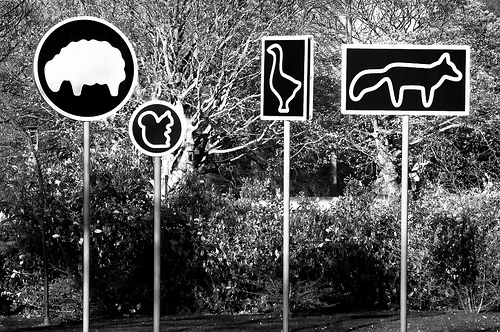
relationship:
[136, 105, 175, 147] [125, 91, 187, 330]
squirrel drawn on sign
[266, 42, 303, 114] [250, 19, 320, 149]
bird drawn on sign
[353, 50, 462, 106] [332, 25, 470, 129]
fox drawn on sign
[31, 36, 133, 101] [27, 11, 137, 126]
sheep drawn on sign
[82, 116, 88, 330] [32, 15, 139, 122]
pole holding up black sign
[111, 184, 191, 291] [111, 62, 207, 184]
pole holding up sign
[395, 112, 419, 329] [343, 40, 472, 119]
pole holding up sign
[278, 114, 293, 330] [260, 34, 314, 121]
pole holding up duck sign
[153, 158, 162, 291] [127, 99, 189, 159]
pole holding up sign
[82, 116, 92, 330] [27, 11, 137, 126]
pole holding up sign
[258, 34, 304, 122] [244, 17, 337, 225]
picture of goose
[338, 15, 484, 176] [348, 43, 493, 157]
symbol of fox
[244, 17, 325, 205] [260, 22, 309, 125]
symbol of bird